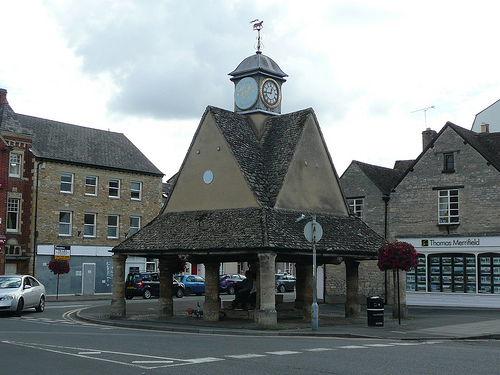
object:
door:
[82, 262, 97, 295]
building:
[105, 17, 391, 329]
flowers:
[375, 240, 420, 271]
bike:
[185, 302, 226, 319]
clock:
[260, 77, 283, 108]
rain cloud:
[38, 0, 375, 124]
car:
[0, 274, 45, 317]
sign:
[54, 244, 72, 261]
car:
[125, 271, 188, 300]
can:
[366, 295, 385, 328]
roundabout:
[0, 278, 497, 375]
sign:
[421, 239, 481, 247]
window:
[403, 252, 499, 295]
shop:
[387, 234, 499, 310]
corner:
[478, 305, 499, 336]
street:
[0, 302, 499, 375]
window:
[59, 172, 75, 194]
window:
[85, 175, 99, 196]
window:
[109, 178, 121, 199]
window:
[59, 210, 72, 237]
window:
[84, 212, 96, 238]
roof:
[13, 113, 167, 176]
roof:
[159, 104, 354, 217]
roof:
[384, 121, 500, 196]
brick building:
[0, 88, 165, 296]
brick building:
[386, 119, 500, 310]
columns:
[111, 252, 409, 329]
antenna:
[411, 104, 438, 130]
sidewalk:
[354, 311, 500, 340]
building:
[314, 117, 438, 305]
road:
[334, 330, 500, 375]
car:
[275, 274, 296, 293]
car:
[219, 273, 247, 295]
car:
[173, 275, 205, 296]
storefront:
[405, 251, 500, 294]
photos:
[406, 257, 500, 295]